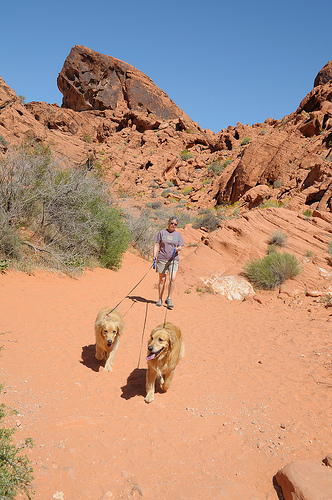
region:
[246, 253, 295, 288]
a green bush in the dirt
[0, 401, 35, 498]
a green bush in the dirt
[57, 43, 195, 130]
a reddish brown jutting rock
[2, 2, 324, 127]
a bright blue sky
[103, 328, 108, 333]
an eye of a dog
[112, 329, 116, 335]
an eye of a dog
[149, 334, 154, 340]
an eye of a dog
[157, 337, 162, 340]
an eye of a dog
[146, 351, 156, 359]
a pink tongue of a dog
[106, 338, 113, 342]
the black nose of a dog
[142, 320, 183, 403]
a golden brown golden retriever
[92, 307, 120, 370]
a golden brown golden retriever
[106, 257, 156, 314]
a blue dog leash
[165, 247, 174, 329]
a blue dog leash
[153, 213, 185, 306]
a person walking dogs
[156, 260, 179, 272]
the tan shorts of a person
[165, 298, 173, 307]
the tan shoe of a person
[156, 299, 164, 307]
the tan shoe of a person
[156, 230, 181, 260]
a grey t-shirt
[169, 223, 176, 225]
a pair of dark sunglasses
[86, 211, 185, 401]
lady walking two dogs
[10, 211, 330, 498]
ground made of red clay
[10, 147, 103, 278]
dried out leafless bushes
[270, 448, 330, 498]
part of a red rock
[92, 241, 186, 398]
two dogs on leashes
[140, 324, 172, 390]
dog with its tongue hanging out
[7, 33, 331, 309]
mountain of large rocks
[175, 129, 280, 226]
scattered green bushes in the mountains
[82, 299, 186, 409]
two golden colored dogs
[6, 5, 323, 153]
a sky with no clouds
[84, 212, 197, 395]
woman walking dogs on dirt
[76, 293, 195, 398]
two dogs walking on dirt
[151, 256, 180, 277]
beige shorts on woman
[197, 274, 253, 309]
white rock in ground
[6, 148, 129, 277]
dry green tree leaning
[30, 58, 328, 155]
rocky landscape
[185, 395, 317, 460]
small rocks on ground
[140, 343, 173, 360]
dog tongue sticking out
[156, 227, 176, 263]
purple shirt on woman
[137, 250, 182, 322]
two leashes for two dogs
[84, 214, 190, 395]
person walking two dogs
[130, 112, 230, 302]
mountain behind person walking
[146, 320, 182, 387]
brown dog with black nose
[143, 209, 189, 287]
person wearing purple shirt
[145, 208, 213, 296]
person holding dog leashes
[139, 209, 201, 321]
person wearing gray shorts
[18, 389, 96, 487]
white and gray stones in dirt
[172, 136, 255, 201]
bushes growing on mountain side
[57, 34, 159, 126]
blue sky behind mountain rock